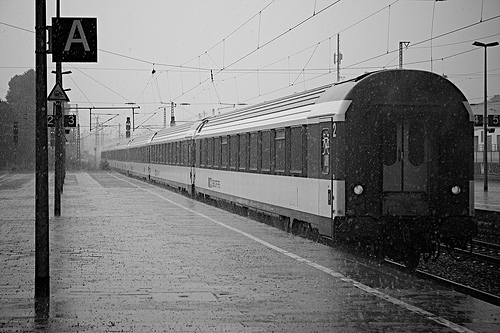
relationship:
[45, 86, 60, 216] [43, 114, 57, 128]
pole with numer 2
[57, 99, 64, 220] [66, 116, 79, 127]
pole with number 3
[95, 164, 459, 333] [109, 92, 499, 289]
strip near platform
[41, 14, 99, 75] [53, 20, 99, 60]
sign have letter a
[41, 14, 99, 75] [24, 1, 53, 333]
sign on post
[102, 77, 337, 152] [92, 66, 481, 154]
lines on train roof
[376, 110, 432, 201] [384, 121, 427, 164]
doors have windows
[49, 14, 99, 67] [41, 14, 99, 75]
sign have letter a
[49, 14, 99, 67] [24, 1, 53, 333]
sign on post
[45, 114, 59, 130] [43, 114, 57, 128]
sign with numer 2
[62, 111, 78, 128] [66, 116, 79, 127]
sign with number 3